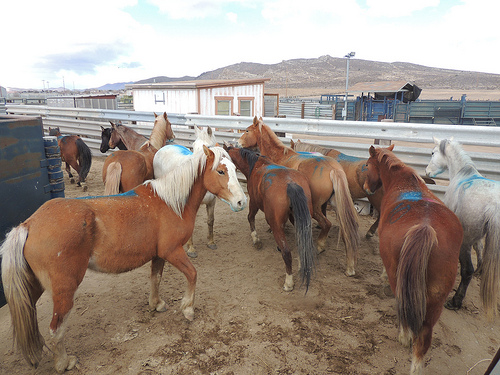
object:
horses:
[289, 139, 387, 241]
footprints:
[138, 232, 431, 373]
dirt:
[1, 149, 500, 375]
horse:
[154, 124, 217, 257]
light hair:
[197, 127, 206, 139]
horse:
[4, 150, 248, 352]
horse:
[355, 144, 468, 375]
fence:
[0, 103, 500, 207]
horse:
[221, 140, 317, 293]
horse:
[237, 115, 362, 279]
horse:
[50, 126, 94, 191]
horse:
[426, 137, 499, 314]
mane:
[146, 144, 228, 219]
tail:
[0, 217, 46, 369]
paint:
[461, 173, 494, 190]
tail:
[286, 184, 318, 297]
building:
[123, 79, 269, 132]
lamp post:
[343, 52, 355, 121]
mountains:
[0, 53, 500, 103]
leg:
[270, 219, 294, 292]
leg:
[148, 255, 171, 313]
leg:
[445, 243, 477, 314]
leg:
[44, 272, 82, 374]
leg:
[71, 158, 88, 191]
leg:
[167, 246, 198, 322]